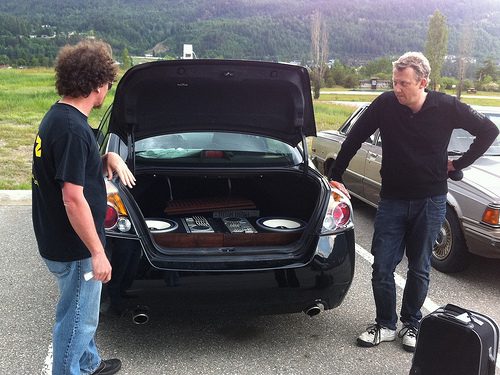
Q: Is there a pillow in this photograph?
A: No, there are no pillows.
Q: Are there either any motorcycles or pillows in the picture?
A: No, there are no pillows or motorcycles.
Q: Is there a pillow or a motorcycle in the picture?
A: No, there are no pillows or motorcycles.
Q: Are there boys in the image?
A: No, there are no boys.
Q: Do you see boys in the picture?
A: No, there are no boys.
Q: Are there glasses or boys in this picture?
A: No, there are no boys or glasses.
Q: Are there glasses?
A: No, there are no glasses.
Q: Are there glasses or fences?
A: No, there are no glasses or fences.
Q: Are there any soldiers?
A: No, there are no soldiers.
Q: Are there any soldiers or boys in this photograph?
A: No, there are no soldiers or boys.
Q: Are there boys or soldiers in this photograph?
A: No, there are no soldiers or boys.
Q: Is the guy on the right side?
A: Yes, the guy is on the right of the image.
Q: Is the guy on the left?
A: No, the guy is on the right of the image.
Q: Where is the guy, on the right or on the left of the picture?
A: The guy is on the right of the image.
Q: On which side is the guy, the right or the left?
A: The guy is on the right of the image.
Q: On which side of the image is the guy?
A: The guy is on the right of the image.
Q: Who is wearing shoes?
A: The guy is wearing shoes.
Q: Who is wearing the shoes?
A: The guy is wearing shoes.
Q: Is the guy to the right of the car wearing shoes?
A: Yes, the guy is wearing shoes.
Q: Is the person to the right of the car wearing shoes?
A: Yes, the guy is wearing shoes.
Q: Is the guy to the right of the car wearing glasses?
A: No, the guy is wearing shoes.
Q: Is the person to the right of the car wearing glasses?
A: No, the guy is wearing shoes.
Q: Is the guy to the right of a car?
A: Yes, the guy is to the right of a car.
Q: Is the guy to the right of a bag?
A: No, the guy is to the right of a car.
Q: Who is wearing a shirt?
A: The guy is wearing a shirt.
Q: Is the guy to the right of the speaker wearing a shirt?
A: Yes, the guy is wearing a shirt.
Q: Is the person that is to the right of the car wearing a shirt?
A: Yes, the guy is wearing a shirt.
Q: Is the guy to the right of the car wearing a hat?
A: No, the guy is wearing a shirt.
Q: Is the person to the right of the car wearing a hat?
A: No, the guy is wearing a shirt.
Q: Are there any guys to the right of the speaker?
A: Yes, there is a guy to the right of the speaker.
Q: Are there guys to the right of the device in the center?
A: Yes, there is a guy to the right of the speaker.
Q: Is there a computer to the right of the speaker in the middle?
A: No, there is a guy to the right of the speaker.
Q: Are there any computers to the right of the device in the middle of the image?
A: No, there is a guy to the right of the speaker.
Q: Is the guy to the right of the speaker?
A: Yes, the guy is to the right of the speaker.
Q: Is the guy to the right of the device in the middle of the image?
A: Yes, the guy is to the right of the speaker.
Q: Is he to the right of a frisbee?
A: No, the guy is to the right of the speaker.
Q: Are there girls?
A: No, there are no girls.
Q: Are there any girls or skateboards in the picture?
A: No, there are no girls or skateboards.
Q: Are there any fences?
A: No, there are no fences.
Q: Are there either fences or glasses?
A: No, there are no fences or glasses.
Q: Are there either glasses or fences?
A: No, there are no fences or glasses.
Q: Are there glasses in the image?
A: No, there are no glasses.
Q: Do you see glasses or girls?
A: No, there are no glasses or girls.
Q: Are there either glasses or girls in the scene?
A: No, there are no glasses or girls.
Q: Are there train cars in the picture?
A: No, there are no train cars.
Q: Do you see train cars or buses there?
A: No, there are no train cars or buses.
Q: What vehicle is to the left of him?
A: The vehicle is a car.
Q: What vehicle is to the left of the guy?
A: The vehicle is a car.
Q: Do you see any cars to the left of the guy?
A: Yes, there is a car to the left of the guy.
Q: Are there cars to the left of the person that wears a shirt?
A: Yes, there is a car to the left of the guy.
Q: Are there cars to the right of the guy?
A: No, the car is to the left of the guy.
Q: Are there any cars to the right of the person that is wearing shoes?
A: No, the car is to the left of the guy.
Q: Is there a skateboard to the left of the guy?
A: No, there is a car to the left of the guy.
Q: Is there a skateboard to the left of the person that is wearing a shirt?
A: No, there is a car to the left of the guy.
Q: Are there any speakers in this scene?
A: Yes, there is a speaker.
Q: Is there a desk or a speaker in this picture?
A: Yes, there is a speaker.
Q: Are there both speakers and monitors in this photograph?
A: No, there is a speaker but no monitors.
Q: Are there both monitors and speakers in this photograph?
A: No, there is a speaker but no monitors.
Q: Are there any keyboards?
A: No, there are no keyboards.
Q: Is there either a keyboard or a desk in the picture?
A: No, there are no keyboards or desks.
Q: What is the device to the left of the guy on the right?
A: The device is a speaker.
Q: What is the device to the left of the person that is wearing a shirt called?
A: The device is a speaker.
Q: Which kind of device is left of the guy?
A: The device is a speaker.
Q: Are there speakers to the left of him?
A: Yes, there is a speaker to the left of the guy.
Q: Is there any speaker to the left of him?
A: Yes, there is a speaker to the left of the guy.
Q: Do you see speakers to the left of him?
A: Yes, there is a speaker to the left of the guy.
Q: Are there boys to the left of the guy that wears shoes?
A: No, there is a speaker to the left of the guy.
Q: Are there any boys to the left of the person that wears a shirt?
A: No, there is a speaker to the left of the guy.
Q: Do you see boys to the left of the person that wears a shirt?
A: No, there is a speaker to the left of the guy.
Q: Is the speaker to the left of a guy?
A: Yes, the speaker is to the left of a guy.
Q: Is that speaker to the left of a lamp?
A: No, the speaker is to the left of a guy.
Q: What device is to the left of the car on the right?
A: The device is a speaker.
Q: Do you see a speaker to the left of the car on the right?
A: Yes, there is a speaker to the left of the car.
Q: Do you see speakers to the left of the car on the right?
A: Yes, there is a speaker to the left of the car.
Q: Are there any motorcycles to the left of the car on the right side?
A: No, there is a speaker to the left of the car.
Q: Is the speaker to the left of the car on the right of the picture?
A: Yes, the speaker is to the left of the car.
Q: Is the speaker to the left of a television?
A: No, the speaker is to the left of the car.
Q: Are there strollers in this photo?
A: No, there are no strollers.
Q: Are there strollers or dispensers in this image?
A: No, there are no strollers or dispensers.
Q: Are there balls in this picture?
A: No, there are no balls.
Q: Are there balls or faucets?
A: No, there are no balls or faucets.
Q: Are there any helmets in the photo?
A: No, there are no helmets.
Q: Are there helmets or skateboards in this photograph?
A: No, there are no helmets or skateboards.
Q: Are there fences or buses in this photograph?
A: No, there are no fences or buses.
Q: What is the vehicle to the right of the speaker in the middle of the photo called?
A: The vehicle is a car.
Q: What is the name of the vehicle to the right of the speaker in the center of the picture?
A: The vehicle is a car.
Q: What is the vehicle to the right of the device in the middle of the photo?
A: The vehicle is a car.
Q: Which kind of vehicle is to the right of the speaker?
A: The vehicle is a car.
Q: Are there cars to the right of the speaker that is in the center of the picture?
A: Yes, there is a car to the right of the speaker.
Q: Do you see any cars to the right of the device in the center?
A: Yes, there is a car to the right of the speaker.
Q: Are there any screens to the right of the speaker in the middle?
A: No, there is a car to the right of the speaker.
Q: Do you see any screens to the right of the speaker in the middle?
A: No, there is a car to the right of the speaker.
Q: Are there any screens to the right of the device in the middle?
A: No, there is a car to the right of the speaker.